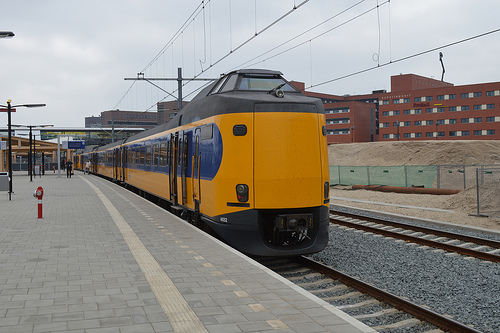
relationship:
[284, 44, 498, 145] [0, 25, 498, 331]
brown building behind train train station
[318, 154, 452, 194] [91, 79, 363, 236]
fence behind train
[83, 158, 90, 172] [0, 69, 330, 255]
man at train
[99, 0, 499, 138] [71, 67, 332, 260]
powerlines above train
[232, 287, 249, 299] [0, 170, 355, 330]
yellow line on ground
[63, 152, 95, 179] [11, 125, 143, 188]
people in station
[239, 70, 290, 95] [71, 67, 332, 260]
windshield on train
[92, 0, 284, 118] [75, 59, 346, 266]
wires over train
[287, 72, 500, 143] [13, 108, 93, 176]
brown building behind train station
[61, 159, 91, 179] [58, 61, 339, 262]
people waiting train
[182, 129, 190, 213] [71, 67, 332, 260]
door side train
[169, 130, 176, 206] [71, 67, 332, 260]
door side train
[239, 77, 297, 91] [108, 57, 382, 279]
windshield on train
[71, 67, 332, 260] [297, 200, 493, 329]
train on track